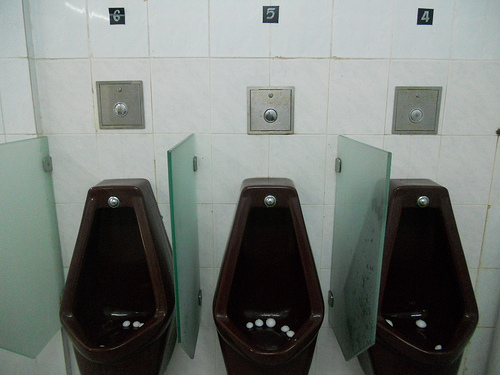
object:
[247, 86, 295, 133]
silver panel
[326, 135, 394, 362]
partition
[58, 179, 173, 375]
bowl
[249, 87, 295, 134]
fixture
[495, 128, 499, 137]
spot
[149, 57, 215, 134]
tile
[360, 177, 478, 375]
urinal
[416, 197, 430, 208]
knob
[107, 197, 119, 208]
knob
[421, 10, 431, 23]
number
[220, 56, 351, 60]
grout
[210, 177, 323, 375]
urinal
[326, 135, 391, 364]
glass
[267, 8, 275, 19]
number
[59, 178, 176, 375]
urinal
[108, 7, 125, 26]
plaque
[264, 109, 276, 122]
flusher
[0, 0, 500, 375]
bathroom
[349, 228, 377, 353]
splash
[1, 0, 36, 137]
mirror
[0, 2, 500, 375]
wall